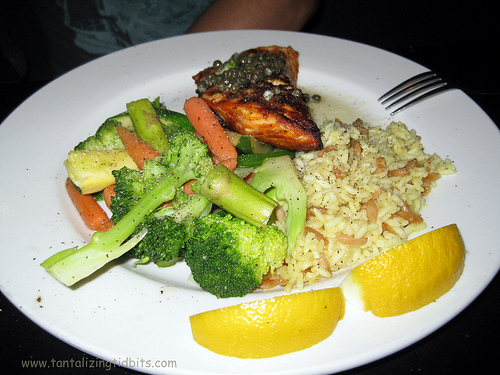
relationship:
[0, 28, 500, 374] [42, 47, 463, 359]
dish contains food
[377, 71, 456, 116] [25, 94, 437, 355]
fork on plate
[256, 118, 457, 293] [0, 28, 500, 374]
rice on dish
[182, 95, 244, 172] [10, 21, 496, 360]
carrots on plates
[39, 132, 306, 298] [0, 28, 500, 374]
vegetable on dish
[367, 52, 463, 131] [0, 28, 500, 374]
fork on dish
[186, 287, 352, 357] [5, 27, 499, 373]
lemon on dish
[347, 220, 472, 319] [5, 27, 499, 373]
lemon on dish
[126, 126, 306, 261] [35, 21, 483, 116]
vegetable on dish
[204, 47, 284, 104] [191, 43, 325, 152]
capers on salmon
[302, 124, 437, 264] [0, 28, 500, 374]
rice on dish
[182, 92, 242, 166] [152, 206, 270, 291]
baby carrots next to broccoli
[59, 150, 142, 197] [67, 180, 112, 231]
sqaush next to carrot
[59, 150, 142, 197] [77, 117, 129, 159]
sqaush next to brocccoli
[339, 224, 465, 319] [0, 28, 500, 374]
lemon on dish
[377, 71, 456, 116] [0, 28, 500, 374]
fork on dish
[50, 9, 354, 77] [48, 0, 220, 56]
person wearing shirt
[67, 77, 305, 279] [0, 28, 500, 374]
broccoli on dish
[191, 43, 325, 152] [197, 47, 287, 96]
salmon with capers